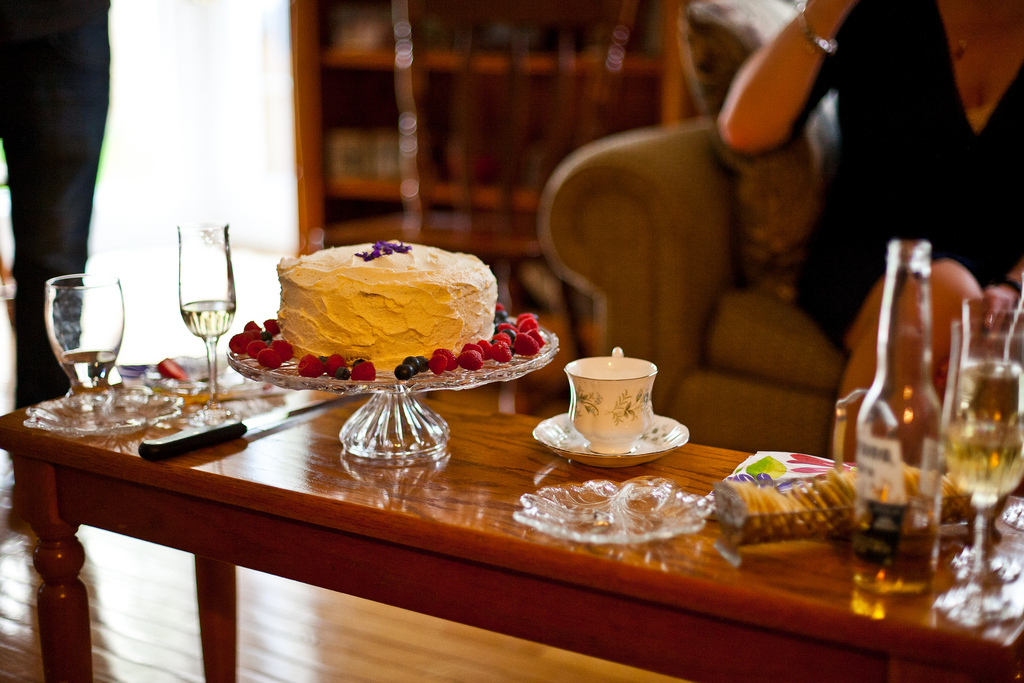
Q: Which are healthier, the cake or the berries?
A: The berries are healthier than the cake.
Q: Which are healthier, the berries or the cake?
A: The berries are healthier than the cake.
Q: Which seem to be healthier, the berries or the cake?
A: The berries are healthier than the cake.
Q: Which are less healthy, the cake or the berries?
A: The cake are less healthy than the berries.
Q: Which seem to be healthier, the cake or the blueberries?
A: The blueberries are healthier than the cake.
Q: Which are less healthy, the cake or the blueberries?
A: The cake are less healthy than the blueberries.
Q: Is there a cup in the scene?
A: Yes, there is a cup.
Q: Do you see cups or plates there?
A: Yes, there is a cup.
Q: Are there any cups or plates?
A: Yes, there is a cup.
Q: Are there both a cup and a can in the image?
A: No, there is a cup but no cans.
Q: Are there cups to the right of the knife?
A: Yes, there is a cup to the right of the knife.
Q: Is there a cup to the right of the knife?
A: Yes, there is a cup to the right of the knife.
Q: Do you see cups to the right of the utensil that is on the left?
A: Yes, there is a cup to the right of the knife.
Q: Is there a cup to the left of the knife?
A: No, the cup is to the right of the knife.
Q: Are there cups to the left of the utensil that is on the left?
A: No, the cup is to the right of the knife.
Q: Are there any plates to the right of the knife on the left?
A: No, there is a cup to the right of the knife.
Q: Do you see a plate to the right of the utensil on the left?
A: No, there is a cup to the right of the knife.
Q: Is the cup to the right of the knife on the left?
A: Yes, the cup is to the right of the knife.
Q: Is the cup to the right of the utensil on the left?
A: Yes, the cup is to the right of the knife.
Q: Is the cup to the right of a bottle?
A: No, the cup is to the right of the knife.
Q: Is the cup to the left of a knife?
A: No, the cup is to the right of a knife.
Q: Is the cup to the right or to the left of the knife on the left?
A: The cup is to the right of the knife.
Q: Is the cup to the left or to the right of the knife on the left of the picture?
A: The cup is to the right of the knife.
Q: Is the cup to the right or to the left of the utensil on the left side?
A: The cup is to the right of the knife.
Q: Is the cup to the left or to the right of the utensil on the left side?
A: The cup is to the right of the knife.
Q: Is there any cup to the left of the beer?
A: Yes, there is a cup to the left of the beer.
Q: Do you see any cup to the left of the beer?
A: Yes, there is a cup to the left of the beer.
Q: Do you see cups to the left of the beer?
A: Yes, there is a cup to the left of the beer.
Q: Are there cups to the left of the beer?
A: Yes, there is a cup to the left of the beer.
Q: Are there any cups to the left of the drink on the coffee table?
A: Yes, there is a cup to the left of the beer.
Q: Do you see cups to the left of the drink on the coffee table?
A: Yes, there is a cup to the left of the beer.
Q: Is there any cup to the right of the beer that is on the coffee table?
A: No, the cup is to the left of the beer.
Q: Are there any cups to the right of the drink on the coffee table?
A: No, the cup is to the left of the beer.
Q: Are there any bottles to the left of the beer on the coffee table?
A: No, there is a cup to the left of the beer.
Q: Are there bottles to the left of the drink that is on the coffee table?
A: No, there is a cup to the left of the beer.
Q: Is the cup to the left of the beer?
A: Yes, the cup is to the left of the beer.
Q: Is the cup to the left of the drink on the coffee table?
A: Yes, the cup is to the left of the beer.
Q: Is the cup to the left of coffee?
A: No, the cup is to the left of the beer.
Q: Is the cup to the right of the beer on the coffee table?
A: No, the cup is to the left of the beer.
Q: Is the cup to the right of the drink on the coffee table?
A: No, the cup is to the left of the beer.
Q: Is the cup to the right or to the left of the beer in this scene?
A: The cup is to the left of the beer.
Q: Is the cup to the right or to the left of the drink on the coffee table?
A: The cup is to the left of the beer.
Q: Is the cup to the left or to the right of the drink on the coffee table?
A: The cup is to the left of the beer.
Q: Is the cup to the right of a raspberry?
A: Yes, the cup is to the right of a raspberry.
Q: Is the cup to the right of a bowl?
A: No, the cup is to the right of a raspberry.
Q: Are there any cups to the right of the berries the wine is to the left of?
A: Yes, there is a cup to the right of the berries.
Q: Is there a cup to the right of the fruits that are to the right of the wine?
A: Yes, there is a cup to the right of the berries.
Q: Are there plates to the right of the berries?
A: No, there is a cup to the right of the berries.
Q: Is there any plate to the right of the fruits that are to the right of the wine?
A: No, there is a cup to the right of the berries.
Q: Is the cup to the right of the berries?
A: Yes, the cup is to the right of the berries.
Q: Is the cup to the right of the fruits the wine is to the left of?
A: Yes, the cup is to the right of the berries.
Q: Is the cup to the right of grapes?
A: No, the cup is to the right of the berries.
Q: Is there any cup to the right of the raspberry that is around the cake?
A: Yes, there is a cup to the right of the raspberry.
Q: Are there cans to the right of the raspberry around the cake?
A: No, there is a cup to the right of the raspberry.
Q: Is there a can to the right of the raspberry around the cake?
A: No, there is a cup to the right of the raspberry.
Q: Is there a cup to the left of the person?
A: Yes, there is a cup to the left of the person.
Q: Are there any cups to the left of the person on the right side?
A: Yes, there is a cup to the left of the person.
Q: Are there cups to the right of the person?
A: No, the cup is to the left of the person.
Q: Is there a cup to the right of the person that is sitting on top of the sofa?
A: No, the cup is to the left of the person.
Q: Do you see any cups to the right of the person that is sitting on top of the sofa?
A: No, the cup is to the left of the person.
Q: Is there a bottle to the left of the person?
A: No, there is a cup to the left of the person.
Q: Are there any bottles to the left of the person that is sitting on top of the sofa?
A: No, there is a cup to the left of the person.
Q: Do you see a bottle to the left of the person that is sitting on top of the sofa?
A: No, there is a cup to the left of the person.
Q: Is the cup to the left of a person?
A: Yes, the cup is to the left of a person.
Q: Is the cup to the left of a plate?
A: No, the cup is to the left of a person.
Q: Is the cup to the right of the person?
A: No, the cup is to the left of the person.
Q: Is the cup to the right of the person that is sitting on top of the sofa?
A: No, the cup is to the left of the person.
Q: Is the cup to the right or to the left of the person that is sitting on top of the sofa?
A: The cup is to the left of the person.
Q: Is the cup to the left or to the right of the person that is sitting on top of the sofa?
A: The cup is to the left of the person.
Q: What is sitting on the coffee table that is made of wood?
A: The cup is sitting on the coffee table.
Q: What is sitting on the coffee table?
A: The cup is sitting on the coffee table.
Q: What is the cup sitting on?
A: The cup is sitting on the coffee table.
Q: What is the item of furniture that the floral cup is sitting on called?
A: The piece of furniture is a coffee table.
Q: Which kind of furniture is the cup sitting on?
A: The cup is sitting on the coffee table.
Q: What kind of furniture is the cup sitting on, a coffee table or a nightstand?
A: The cup is sitting on a coffee table.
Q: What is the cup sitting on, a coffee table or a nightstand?
A: The cup is sitting on a coffee table.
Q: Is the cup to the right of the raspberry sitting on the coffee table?
A: Yes, the cup is sitting on the coffee table.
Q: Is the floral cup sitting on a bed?
A: No, the cup is sitting on the coffee table.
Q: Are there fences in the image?
A: No, there are no fences.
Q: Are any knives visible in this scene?
A: Yes, there is a knife.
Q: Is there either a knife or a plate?
A: Yes, there is a knife.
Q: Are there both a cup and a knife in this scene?
A: Yes, there are both a knife and a cup.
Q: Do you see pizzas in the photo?
A: No, there are no pizzas.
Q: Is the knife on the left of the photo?
A: Yes, the knife is on the left of the image.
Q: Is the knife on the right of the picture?
A: No, the knife is on the left of the image.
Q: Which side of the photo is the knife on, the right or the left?
A: The knife is on the left of the image.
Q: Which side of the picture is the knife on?
A: The knife is on the left of the image.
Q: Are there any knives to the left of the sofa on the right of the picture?
A: Yes, there is a knife to the left of the sofa.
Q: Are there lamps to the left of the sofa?
A: No, there is a knife to the left of the sofa.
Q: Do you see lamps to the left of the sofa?
A: No, there is a knife to the left of the sofa.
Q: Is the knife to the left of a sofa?
A: Yes, the knife is to the left of a sofa.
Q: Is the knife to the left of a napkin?
A: No, the knife is to the left of a sofa.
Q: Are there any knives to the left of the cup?
A: Yes, there is a knife to the left of the cup.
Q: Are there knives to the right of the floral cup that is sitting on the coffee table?
A: No, the knife is to the left of the cup.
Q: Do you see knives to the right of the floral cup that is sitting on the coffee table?
A: No, the knife is to the left of the cup.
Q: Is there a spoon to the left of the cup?
A: No, there is a knife to the left of the cup.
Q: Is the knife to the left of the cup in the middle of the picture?
A: Yes, the knife is to the left of the cup.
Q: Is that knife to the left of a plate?
A: No, the knife is to the left of the cup.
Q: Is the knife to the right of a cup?
A: No, the knife is to the left of a cup.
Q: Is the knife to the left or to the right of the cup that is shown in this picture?
A: The knife is to the left of the cup.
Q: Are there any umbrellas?
A: No, there are no umbrellas.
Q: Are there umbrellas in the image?
A: No, there are no umbrellas.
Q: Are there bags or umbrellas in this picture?
A: No, there are no umbrellas or bags.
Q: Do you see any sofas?
A: Yes, there is a sofa.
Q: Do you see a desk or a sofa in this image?
A: Yes, there is a sofa.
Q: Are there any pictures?
A: No, there are no pictures.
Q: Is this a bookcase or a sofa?
A: This is a sofa.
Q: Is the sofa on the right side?
A: Yes, the sofa is on the right of the image.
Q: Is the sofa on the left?
A: No, the sofa is on the right of the image.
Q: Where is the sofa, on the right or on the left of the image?
A: The sofa is on the right of the image.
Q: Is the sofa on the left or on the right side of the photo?
A: The sofa is on the right of the image.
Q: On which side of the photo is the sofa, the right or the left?
A: The sofa is on the right of the image.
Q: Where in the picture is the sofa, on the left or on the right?
A: The sofa is on the right of the image.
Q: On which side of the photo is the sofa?
A: The sofa is on the right of the image.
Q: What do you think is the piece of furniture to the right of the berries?
A: The piece of furniture is a sofa.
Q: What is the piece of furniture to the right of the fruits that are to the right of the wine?
A: The piece of furniture is a sofa.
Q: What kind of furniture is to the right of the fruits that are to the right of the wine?
A: The piece of furniture is a sofa.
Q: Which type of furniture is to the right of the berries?
A: The piece of furniture is a sofa.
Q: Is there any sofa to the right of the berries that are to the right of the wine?
A: Yes, there is a sofa to the right of the berries.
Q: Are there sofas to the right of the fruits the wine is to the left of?
A: Yes, there is a sofa to the right of the berries.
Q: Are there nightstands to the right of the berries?
A: No, there is a sofa to the right of the berries.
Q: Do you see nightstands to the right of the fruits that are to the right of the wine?
A: No, there is a sofa to the right of the berries.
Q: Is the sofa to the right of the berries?
A: Yes, the sofa is to the right of the berries.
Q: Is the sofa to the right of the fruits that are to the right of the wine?
A: Yes, the sofa is to the right of the berries.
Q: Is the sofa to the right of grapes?
A: No, the sofa is to the right of the berries.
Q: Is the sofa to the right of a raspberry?
A: Yes, the sofa is to the right of a raspberry.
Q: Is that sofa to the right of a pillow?
A: No, the sofa is to the right of a raspberry.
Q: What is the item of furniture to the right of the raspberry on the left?
A: The piece of furniture is a sofa.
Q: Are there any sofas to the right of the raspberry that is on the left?
A: Yes, there is a sofa to the right of the raspberry.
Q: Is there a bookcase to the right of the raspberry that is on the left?
A: No, there is a sofa to the right of the raspberry.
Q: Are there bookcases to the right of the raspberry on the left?
A: No, there is a sofa to the right of the raspberry.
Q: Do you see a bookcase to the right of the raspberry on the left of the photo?
A: No, there is a sofa to the right of the raspberry.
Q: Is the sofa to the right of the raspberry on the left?
A: Yes, the sofa is to the right of the raspberry.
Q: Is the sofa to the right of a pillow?
A: No, the sofa is to the right of the raspberry.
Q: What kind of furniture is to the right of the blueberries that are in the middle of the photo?
A: The piece of furniture is a sofa.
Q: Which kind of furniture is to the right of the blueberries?
A: The piece of furniture is a sofa.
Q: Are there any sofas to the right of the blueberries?
A: Yes, there is a sofa to the right of the blueberries.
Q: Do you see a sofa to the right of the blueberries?
A: Yes, there is a sofa to the right of the blueberries.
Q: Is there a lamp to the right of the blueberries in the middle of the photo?
A: No, there is a sofa to the right of the blueberries.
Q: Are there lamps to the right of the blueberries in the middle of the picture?
A: No, there is a sofa to the right of the blueberries.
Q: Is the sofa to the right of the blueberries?
A: Yes, the sofa is to the right of the blueberries.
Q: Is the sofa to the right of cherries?
A: No, the sofa is to the right of the blueberries.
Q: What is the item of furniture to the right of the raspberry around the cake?
A: The piece of furniture is a sofa.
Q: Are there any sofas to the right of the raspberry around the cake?
A: Yes, there is a sofa to the right of the raspberry.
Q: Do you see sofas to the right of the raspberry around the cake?
A: Yes, there is a sofa to the right of the raspberry.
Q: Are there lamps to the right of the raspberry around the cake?
A: No, there is a sofa to the right of the raspberry.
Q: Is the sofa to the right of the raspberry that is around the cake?
A: Yes, the sofa is to the right of the raspberry.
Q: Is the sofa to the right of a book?
A: No, the sofa is to the right of the raspberry.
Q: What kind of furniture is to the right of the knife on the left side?
A: The piece of furniture is a sofa.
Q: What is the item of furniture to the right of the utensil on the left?
A: The piece of furniture is a sofa.